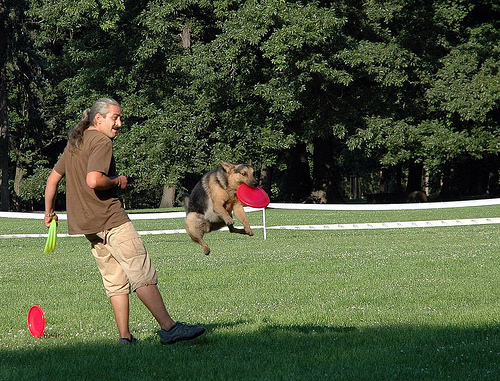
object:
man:
[44, 96, 206, 346]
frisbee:
[43, 221, 51, 253]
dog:
[183, 158, 261, 255]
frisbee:
[236, 182, 270, 208]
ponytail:
[66, 107, 91, 156]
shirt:
[53, 128, 132, 235]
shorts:
[84, 221, 159, 298]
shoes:
[117, 333, 142, 346]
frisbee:
[27, 303, 46, 339]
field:
[0, 0, 499, 379]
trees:
[0, 0, 499, 211]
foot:
[155, 320, 207, 345]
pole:
[262, 207, 267, 240]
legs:
[95, 220, 176, 328]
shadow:
[0, 317, 499, 380]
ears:
[219, 159, 237, 171]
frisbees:
[52, 218, 57, 252]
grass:
[0, 206, 499, 380]